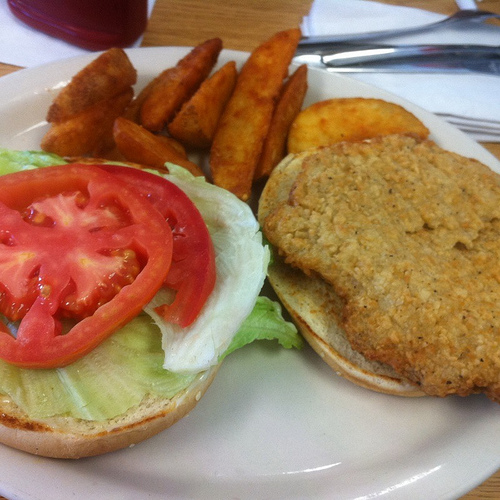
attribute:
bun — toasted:
[43, 363, 188, 463]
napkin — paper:
[297, 0, 497, 69]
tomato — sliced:
[1, 167, 205, 371]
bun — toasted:
[269, 253, 435, 428]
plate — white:
[0, 30, 488, 497]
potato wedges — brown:
[43, 48, 142, 120]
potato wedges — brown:
[214, 25, 305, 192]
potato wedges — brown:
[137, 30, 226, 129]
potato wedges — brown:
[112, 113, 199, 172]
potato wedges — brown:
[167, 59, 238, 147]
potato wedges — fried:
[45, 26, 430, 196]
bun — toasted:
[0, 382, 217, 462]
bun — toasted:
[262, 150, 412, 395]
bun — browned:
[0, 368, 197, 469]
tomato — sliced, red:
[0, 166, 175, 371]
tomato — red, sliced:
[79, 161, 216, 326]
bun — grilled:
[3, 372, 215, 464]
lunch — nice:
[1, 25, 498, 460]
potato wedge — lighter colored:
[287, 97, 428, 150]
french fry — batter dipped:
[44, 49, 136, 125]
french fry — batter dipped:
[43, 91, 135, 157]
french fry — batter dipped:
[112, 117, 202, 184]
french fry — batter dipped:
[213, 28, 302, 200]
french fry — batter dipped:
[287, 98, 428, 154]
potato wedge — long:
[208, 25, 305, 203]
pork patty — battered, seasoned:
[262, 130, 499, 407]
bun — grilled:
[6, 401, 203, 460]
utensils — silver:
[299, 32, 497, 73]